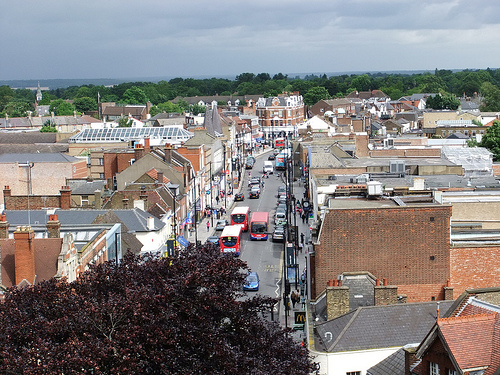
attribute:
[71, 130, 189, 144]
roof — glass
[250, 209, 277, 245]
bus — city bus, red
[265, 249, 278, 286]
street — narrow, full of traffic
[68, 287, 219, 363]
tree — large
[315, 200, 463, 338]
building — multi storied, brick, multi story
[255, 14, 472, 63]
sky — cloudy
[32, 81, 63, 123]
church — tall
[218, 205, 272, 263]
buses — on street, red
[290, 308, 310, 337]
sign — golden arches, for mcdonalds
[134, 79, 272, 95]
trees — in background, green, on the horizon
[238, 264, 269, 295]
car — blue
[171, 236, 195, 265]
letter — yellow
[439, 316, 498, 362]
roof — red